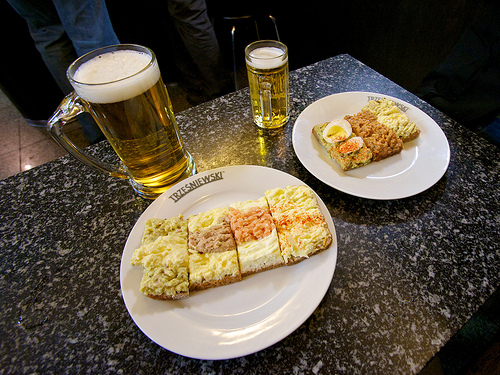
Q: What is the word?
A: Trzesniewski.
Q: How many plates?
A: Two.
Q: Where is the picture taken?
A: In a restaurant.